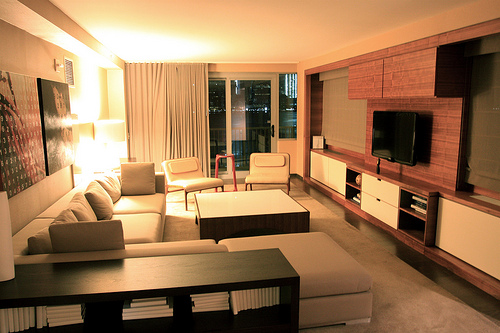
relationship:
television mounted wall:
[372, 110, 419, 166] [316, 26, 496, 202]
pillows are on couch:
[96, 158, 155, 201] [56, 162, 169, 251]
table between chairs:
[208, 148, 242, 193] [151, 149, 305, 193]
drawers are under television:
[359, 166, 401, 227] [372, 110, 419, 166]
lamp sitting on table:
[88, 116, 128, 169] [93, 157, 122, 177]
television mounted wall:
[365, 105, 436, 170] [304, 54, 498, 236]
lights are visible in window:
[208, 82, 298, 119] [207, 62, 301, 161]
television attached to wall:
[372, 110, 419, 166] [299, 50, 481, 277]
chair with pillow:
[26, 166, 376, 318] [80, 177, 110, 222]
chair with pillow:
[26, 166, 376, 318] [120, 160, 158, 193]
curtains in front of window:
[119, 61, 209, 178] [211, 74, 301, 178]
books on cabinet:
[3, 305, 87, 325] [10, 249, 301, 328]